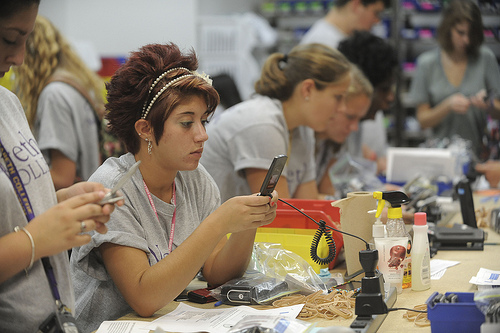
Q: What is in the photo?
A: Table.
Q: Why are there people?
A: Customers.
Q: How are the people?
A: Busy.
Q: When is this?
A: Daytime.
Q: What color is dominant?
A: Gray.